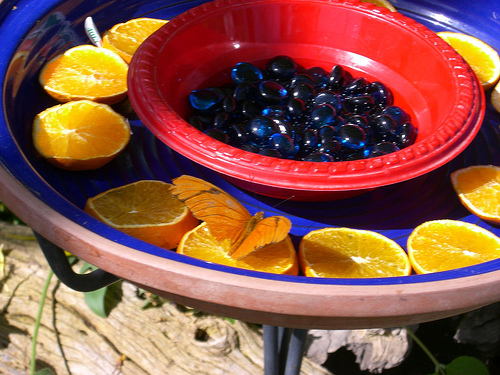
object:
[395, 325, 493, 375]
leaves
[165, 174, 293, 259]
butterfly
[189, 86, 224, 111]
pebbles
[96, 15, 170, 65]
orange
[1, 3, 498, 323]
platter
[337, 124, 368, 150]
gems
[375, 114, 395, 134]
gems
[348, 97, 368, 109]
gems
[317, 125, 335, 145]
gems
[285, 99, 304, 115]
gems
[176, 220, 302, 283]
orange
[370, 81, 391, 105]
jewel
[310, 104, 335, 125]
jewel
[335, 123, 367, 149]
jewel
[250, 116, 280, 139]
jewel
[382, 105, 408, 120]
jewel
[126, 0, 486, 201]
bowl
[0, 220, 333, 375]
wood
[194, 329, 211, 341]
hole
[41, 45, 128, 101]
fruit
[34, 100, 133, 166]
fruit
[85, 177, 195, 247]
fruit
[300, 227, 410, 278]
fruit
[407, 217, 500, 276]
fruit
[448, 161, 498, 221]
orange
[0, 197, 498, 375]
ground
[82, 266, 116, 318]
leaf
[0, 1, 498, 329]
bowl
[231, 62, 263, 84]
pebbles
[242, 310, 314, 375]
metal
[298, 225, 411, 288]
fruit